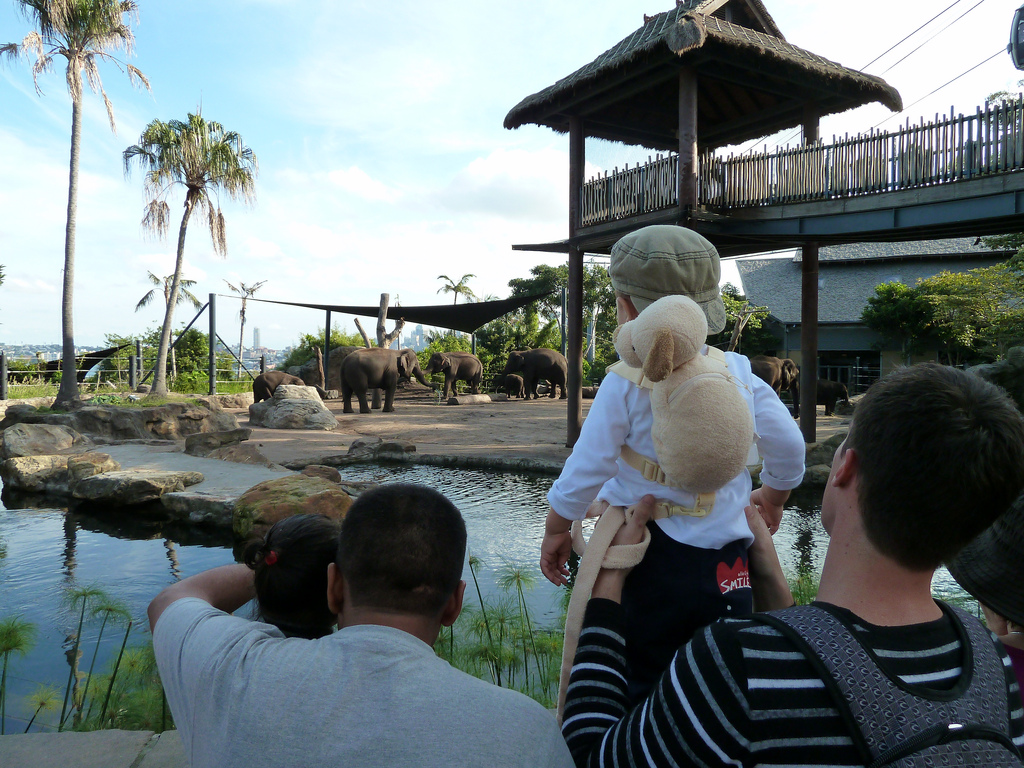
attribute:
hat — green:
[607, 221, 738, 333]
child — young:
[536, 222, 816, 688]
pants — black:
[597, 510, 771, 735]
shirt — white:
[125, 596, 577, 762]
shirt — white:
[565, 592, 1015, 760]